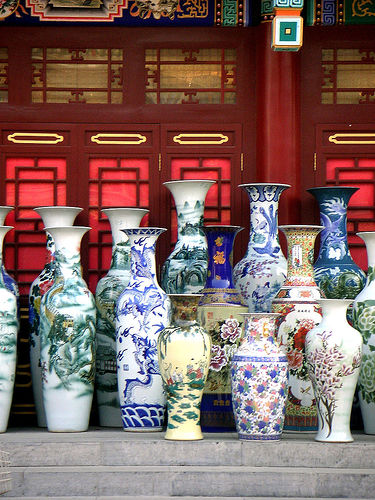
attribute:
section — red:
[89, 158, 116, 179]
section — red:
[119, 155, 150, 181]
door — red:
[4, 123, 79, 301]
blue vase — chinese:
[195, 221, 245, 442]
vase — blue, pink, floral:
[226, 308, 291, 441]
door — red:
[0, 120, 76, 300]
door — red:
[1, 118, 245, 429]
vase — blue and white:
[159, 287, 213, 445]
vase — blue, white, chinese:
[223, 151, 296, 302]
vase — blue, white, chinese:
[113, 226, 172, 432]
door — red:
[165, 125, 237, 231]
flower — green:
[291, 324, 315, 352]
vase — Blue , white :
[108, 229, 171, 445]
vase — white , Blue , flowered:
[109, 222, 174, 430]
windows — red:
[4, 154, 232, 297]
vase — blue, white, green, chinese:
[305, 178, 371, 307]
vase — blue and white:
[220, 159, 282, 390]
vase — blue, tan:
[196, 222, 245, 433]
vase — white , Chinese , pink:
[303, 296, 363, 443]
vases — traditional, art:
[4, 177, 373, 443]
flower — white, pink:
[216, 316, 243, 343]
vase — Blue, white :
[232, 293, 293, 431]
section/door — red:
[20, 184, 51, 203]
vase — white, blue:
[117, 276, 262, 453]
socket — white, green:
[271, 11, 305, 58]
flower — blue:
[243, 369, 253, 379]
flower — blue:
[268, 369, 278, 379]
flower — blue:
[238, 422, 246, 429]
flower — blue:
[256, 420, 266, 429]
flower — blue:
[272, 422, 280, 431]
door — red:
[3, 27, 253, 327]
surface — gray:
[2, 424, 374, 496]